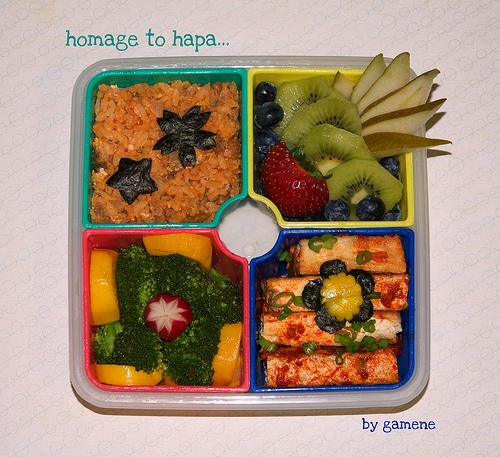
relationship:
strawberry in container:
[264, 139, 324, 201] [68, 43, 440, 441]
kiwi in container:
[276, 76, 403, 213] [248, 67, 415, 226]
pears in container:
[343, 70, 441, 152] [71, 55, 431, 415]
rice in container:
[90, 81, 243, 227] [57, 55, 497, 372]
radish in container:
[144, 290, 191, 342] [68, 43, 440, 441]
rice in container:
[103, 81, 255, 224] [71, 55, 431, 415]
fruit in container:
[252, 49, 453, 221] [71, 55, 431, 415]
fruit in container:
[270, 82, 394, 217] [71, 55, 431, 415]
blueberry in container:
[378, 155, 399, 174] [71, 55, 431, 415]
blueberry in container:
[357, 195, 385, 222] [71, 55, 431, 415]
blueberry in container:
[324, 197, 349, 221] [71, 55, 431, 415]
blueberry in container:
[257, 102, 282, 127] [71, 55, 431, 415]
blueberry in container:
[252, 80, 278, 106] [71, 55, 431, 415]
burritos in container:
[263, 235, 413, 388] [71, 55, 431, 415]